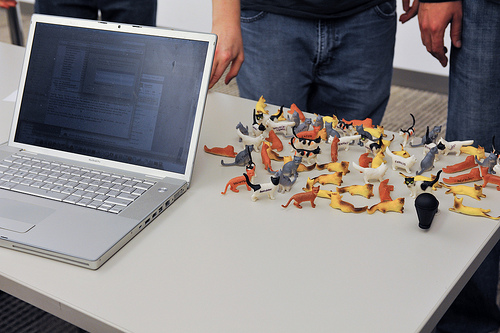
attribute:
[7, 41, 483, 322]
table — long, white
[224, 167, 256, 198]
figurine — small, orange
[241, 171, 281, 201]
figurine — black, white, small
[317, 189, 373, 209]
figurine — small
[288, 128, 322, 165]
figurines — small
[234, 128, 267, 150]
figurine — white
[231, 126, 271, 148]
fur — long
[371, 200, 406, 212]
action figure — small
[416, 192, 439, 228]
action figure — small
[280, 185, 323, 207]
cat figurine — small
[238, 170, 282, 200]
cat figurine — small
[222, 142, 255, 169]
cat figurine — small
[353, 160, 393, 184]
cat figurine — small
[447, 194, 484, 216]
cat figurine — small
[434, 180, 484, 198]
cat figurine — small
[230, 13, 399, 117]
jeans — blue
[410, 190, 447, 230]
figurine — black, large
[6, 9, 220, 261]
laptop — silver, metal